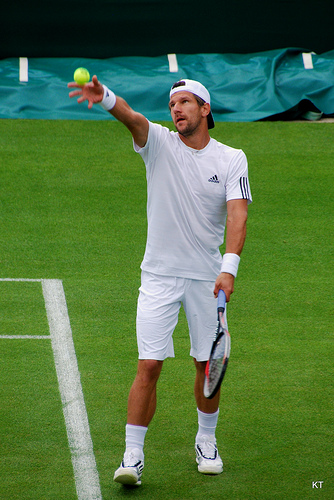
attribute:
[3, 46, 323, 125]
tarp — green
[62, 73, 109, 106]
hand — extended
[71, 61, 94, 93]
ball — yellow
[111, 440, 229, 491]
shoes — white, blue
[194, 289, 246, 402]
tennis racket — black, red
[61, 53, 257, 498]
man — leg, wearing shorts, tennis player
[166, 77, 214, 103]
hat — backwards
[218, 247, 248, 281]
wrist — white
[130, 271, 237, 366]
shorts — white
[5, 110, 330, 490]
grass — green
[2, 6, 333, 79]
background — dark